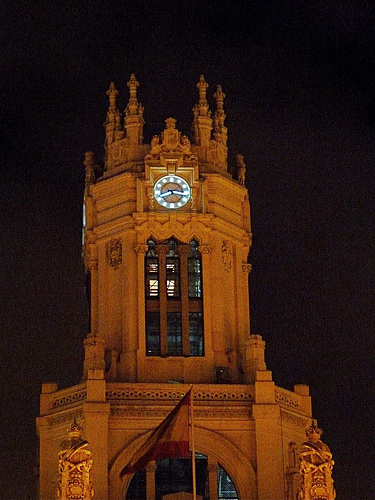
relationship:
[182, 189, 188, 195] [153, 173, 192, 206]
3 on clock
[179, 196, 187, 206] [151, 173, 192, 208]
number on clock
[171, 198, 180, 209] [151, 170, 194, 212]
6 on clock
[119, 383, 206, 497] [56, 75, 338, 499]
flag on front of building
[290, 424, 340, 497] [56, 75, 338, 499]
carved stone on building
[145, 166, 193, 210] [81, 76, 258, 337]
clock on tower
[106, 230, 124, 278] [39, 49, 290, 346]
decorative on building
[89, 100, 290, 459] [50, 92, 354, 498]
wall on building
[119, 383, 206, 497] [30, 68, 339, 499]
flag on building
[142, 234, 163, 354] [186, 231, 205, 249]
window has pointed top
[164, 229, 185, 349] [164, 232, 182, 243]
window has pointed top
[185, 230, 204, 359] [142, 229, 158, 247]
window has pointed top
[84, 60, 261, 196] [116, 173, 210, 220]
spikes are above clock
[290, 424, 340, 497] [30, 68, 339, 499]
carved stone in front of building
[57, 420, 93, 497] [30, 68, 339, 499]
carved stone in front of building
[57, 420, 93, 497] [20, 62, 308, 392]
carved stone in front of building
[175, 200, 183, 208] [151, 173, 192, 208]
5 on clock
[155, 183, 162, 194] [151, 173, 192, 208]
9 on clock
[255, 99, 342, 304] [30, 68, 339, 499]
nighttime outside of building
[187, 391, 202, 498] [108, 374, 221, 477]
pole of flag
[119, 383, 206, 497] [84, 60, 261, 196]
flag near spikes